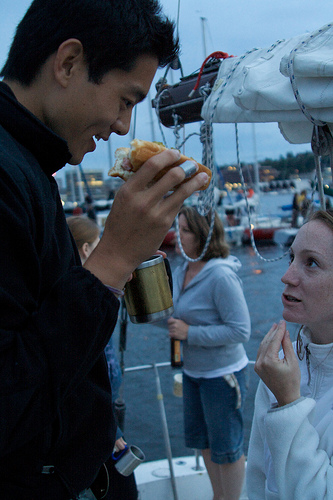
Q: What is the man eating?
A: Hot dog.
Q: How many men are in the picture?
A: One.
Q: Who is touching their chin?
A: Woman talking to man.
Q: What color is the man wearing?
A: Black.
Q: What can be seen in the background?
A: Boats.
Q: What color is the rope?
A: Blue and white.